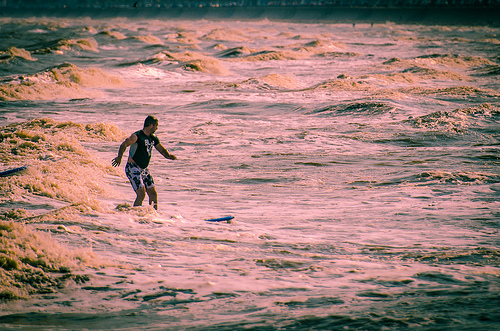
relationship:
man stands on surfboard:
[106, 112, 181, 215] [112, 206, 269, 234]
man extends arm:
[106, 112, 181, 215] [112, 131, 132, 169]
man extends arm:
[106, 112, 181, 215] [151, 136, 177, 159]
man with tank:
[106, 112, 181, 215] [131, 130, 157, 169]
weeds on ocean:
[4, 115, 120, 295] [0, 16, 500, 331]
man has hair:
[106, 112, 181, 215] [136, 112, 160, 129]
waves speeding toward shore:
[29, 112, 129, 138] [334, 311, 494, 329]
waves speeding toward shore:
[2, 266, 94, 296] [334, 311, 494, 329]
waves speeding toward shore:
[0, 223, 88, 265] [334, 311, 494, 329]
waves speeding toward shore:
[34, 201, 99, 218] [334, 311, 494, 329]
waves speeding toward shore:
[12, 139, 89, 168] [334, 311, 494, 329]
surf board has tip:
[105, 105, 232, 254] [207, 214, 237, 224]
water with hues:
[0, 19, 498, 327] [30, 22, 480, 310]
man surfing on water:
[109, 114, 236, 223] [14, 24, 477, 307]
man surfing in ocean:
[106, 112, 181, 215] [4, 12, 495, 329]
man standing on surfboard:
[106, 112, 181, 215] [196, 209, 236, 224]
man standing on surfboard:
[106, 112, 181, 215] [205, 213, 232, 220]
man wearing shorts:
[106, 112, 181, 215] [124, 163, 157, 192]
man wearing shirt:
[106, 112, 181, 215] [127, 128, 158, 165]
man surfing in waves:
[106, 112, 181, 215] [1, 0, 498, 329]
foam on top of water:
[8, 117, 103, 212] [220, 134, 412, 296]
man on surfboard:
[106, 112, 181, 215] [123, 212, 232, 222]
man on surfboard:
[106, 112, 181, 215] [112, 195, 262, 250]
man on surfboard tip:
[106, 112, 181, 215] [202, 214, 239, 224]